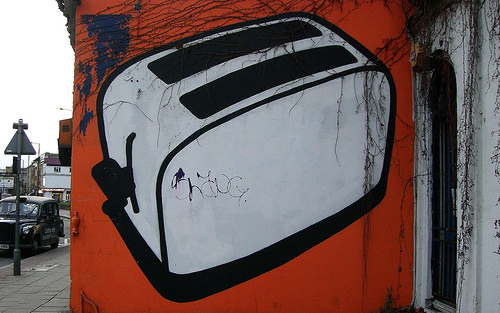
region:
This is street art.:
[83, 18, 440, 288]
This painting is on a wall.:
[62, 12, 409, 311]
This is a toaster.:
[99, 25, 407, 252]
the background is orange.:
[280, 268, 368, 310]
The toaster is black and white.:
[89, 25, 397, 300]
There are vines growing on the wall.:
[366, 18, 498, 176]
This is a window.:
[408, 32, 496, 311]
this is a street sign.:
[6, 108, 44, 215]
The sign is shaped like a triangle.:
[11, 103, 53, 185]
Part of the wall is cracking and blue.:
[76, 9, 133, 91]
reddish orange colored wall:
[68, 1, 418, 311]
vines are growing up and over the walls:
[353, 3, 498, 310]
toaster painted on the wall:
[92, 10, 399, 304]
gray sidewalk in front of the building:
[2, 251, 68, 310]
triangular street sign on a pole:
[3, 118, 39, 275]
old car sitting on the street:
[1, 193, 63, 255]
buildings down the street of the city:
[1, 153, 71, 204]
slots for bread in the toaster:
[146, 16, 364, 121]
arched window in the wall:
[423, 43, 461, 310]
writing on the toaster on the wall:
[168, 163, 254, 208]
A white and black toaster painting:
[92, 30, 391, 270]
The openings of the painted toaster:
[141, 32, 352, 99]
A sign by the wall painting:
[3, 122, 34, 273]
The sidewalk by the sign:
[17, 272, 64, 304]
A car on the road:
[2, 190, 54, 245]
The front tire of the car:
[30, 230, 40, 255]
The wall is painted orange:
[80, 242, 117, 288]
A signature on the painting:
[166, 167, 252, 200]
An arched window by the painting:
[421, 53, 461, 305]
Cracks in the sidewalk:
[10, 286, 64, 305]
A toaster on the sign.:
[80, 4, 389, 284]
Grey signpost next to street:
[13, 120, 19, 275]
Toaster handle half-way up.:
[91, 128, 143, 213]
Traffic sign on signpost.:
[2, 118, 37, 155]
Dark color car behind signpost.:
[0, 196, 61, 251]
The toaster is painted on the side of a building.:
[75, 1, 415, 301]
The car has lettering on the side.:
[37, 225, 57, 240]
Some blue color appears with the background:
[77, 10, 94, 131]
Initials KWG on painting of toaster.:
[180, 166, 250, 197]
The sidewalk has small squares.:
[8, 274, 65, 301]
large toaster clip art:
[79, 5, 419, 309]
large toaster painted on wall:
[88, 7, 429, 309]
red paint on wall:
[335, 240, 394, 297]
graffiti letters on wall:
[172, 164, 259, 208]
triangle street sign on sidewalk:
[0, 114, 42, 283]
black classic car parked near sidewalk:
[2, 191, 67, 256]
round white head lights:
[17, 219, 36, 239]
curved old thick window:
[412, 39, 464, 311]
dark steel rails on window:
[416, 51, 471, 309]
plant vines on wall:
[79, 4, 140, 57]